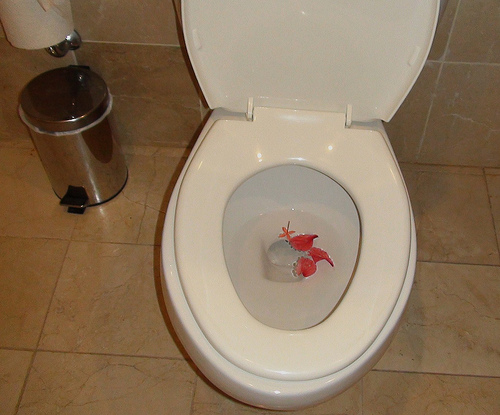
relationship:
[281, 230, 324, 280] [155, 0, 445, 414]
petals inside toilet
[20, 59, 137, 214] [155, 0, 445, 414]
can next to toilet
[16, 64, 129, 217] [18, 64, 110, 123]
can has garbage bag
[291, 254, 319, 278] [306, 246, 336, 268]
flower petals of petals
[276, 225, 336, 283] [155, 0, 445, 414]
petals in toilet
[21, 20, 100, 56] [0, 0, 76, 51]
holder with toilet paper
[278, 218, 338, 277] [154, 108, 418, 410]
flower petals are in toilet bowl.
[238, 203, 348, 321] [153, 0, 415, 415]
water in toilet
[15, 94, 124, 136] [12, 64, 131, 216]
garbage bag in can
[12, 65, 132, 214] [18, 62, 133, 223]
trash inside can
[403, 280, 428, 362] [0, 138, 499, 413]
shadow on floor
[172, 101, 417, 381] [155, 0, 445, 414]
seat on toilet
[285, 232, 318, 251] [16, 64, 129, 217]
petals for opening can